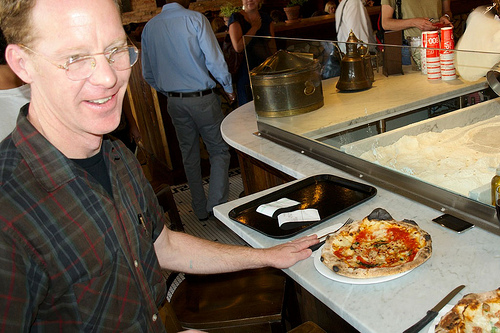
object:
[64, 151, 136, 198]
undershirt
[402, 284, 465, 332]
knife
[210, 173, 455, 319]
counter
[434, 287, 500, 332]
pizza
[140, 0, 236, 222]
man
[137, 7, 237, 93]
shirt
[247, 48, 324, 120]
tin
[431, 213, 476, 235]
cell phone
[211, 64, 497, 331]
counter top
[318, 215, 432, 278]
food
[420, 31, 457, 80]
paper cups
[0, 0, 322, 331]
man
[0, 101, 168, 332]
plaid shirt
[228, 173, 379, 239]
tray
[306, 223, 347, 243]
napkin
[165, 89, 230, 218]
gray pants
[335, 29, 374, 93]
pitcher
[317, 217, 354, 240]
fork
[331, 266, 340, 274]
burnt mark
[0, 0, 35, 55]
hair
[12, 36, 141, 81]
glasses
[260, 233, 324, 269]
hand